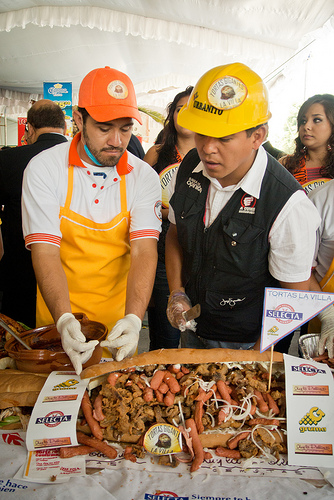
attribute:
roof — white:
[35, 33, 70, 48]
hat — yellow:
[173, 85, 253, 136]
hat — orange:
[72, 61, 148, 127]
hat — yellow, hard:
[173, 59, 276, 136]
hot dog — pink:
[182, 416, 207, 474]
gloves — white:
[50, 306, 145, 380]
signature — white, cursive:
[218, 294, 243, 306]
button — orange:
[82, 167, 119, 205]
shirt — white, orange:
[15, 136, 169, 251]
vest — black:
[167, 144, 303, 345]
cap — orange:
[74, 60, 143, 129]